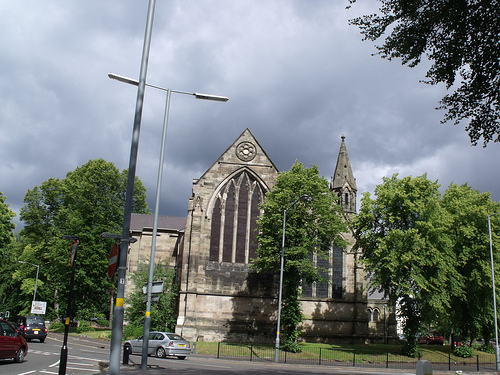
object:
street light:
[194, 92, 228, 103]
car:
[125, 332, 191, 360]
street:
[0, 332, 500, 374]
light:
[192, 344, 197, 351]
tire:
[17, 348, 27, 363]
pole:
[103, 3, 156, 374]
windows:
[208, 168, 271, 267]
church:
[130, 128, 417, 345]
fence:
[195, 343, 499, 371]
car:
[0, 317, 28, 363]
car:
[14, 314, 46, 342]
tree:
[258, 160, 346, 355]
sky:
[0, 0, 110, 164]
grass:
[322, 339, 353, 361]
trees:
[361, 171, 461, 360]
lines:
[20, 352, 109, 374]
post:
[272, 206, 298, 363]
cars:
[120, 331, 195, 360]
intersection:
[2, 327, 111, 374]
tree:
[16, 160, 147, 326]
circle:
[236, 140, 255, 163]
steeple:
[330, 132, 356, 189]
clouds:
[175, 0, 327, 115]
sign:
[105, 242, 120, 276]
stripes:
[107, 296, 129, 310]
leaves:
[393, 40, 414, 60]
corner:
[58, 314, 499, 358]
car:
[421, 331, 443, 345]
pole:
[59, 240, 82, 375]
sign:
[69, 240, 78, 268]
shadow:
[223, 272, 287, 348]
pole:
[139, 90, 181, 368]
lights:
[105, 69, 143, 87]